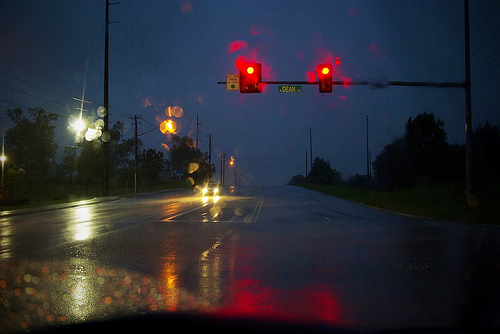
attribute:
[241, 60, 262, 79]
light — part, red, orange, white, reflecting, traffic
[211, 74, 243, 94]
sign — yield, green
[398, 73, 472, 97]
pole — electric, power, utility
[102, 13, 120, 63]
lines — powered, distant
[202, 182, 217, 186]
car — oncoming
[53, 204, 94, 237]
pavement — wet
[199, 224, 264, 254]
road — wet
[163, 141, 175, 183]
post — part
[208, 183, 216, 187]
window — part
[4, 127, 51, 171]
trees — part, lined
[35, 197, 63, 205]
grass — part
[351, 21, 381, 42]
sky — part, dark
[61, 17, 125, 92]
poles — electric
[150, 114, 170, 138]
streetlight — shining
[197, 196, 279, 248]
roadway — wet